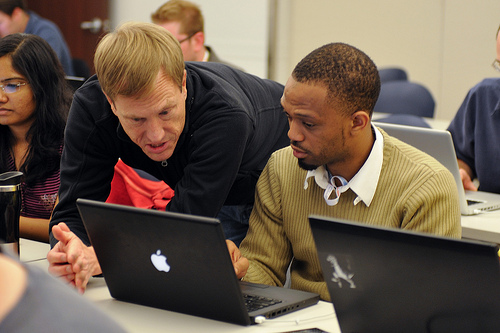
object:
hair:
[92, 20, 190, 110]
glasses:
[0, 82, 28, 91]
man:
[223, 43, 463, 304]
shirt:
[47, 59, 296, 252]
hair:
[291, 41, 381, 119]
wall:
[266, 0, 500, 121]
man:
[47, 23, 291, 295]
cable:
[256, 300, 337, 327]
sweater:
[239, 125, 462, 301]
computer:
[77, 197, 322, 326]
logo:
[325, 250, 362, 288]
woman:
[1, 32, 65, 243]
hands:
[226, 239, 250, 280]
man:
[152, 2, 236, 66]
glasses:
[177, 31, 197, 44]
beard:
[291, 142, 348, 170]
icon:
[150, 249, 173, 274]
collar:
[301, 121, 384, 207]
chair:
[371, 67, 436, 118]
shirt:
[448, 78, 500, 194]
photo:
[0, 2, 500, 332]